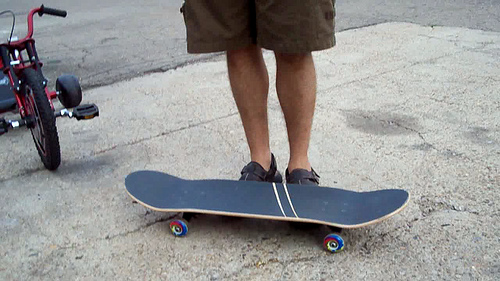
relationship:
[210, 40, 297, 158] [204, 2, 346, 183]
leg of man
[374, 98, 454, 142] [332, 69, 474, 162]
crack in pavement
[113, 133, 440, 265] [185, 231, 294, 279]
skateboard on ground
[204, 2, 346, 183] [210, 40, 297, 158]
man has leg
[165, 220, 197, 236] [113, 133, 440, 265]
wheel of skateboard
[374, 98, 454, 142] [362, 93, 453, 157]
crack in concrete